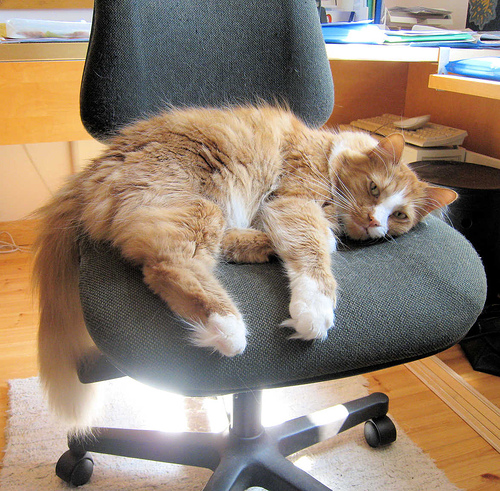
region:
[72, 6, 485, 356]
orange and white cat lying across gray office chair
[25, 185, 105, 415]
fluffy tail hanging off side of chair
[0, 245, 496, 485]
white rug on wood floor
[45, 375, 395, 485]
black chair base and wheels on rug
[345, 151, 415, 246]
cat with grouchy expression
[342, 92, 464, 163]
mouse and keyboard on box in corner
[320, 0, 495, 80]
desk filled with papers, notebook, pens and artwork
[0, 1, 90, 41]
plastic container with flat item inside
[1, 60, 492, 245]
wooden wall underneath desk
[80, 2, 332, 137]
woven fabric with fuzzy loops on back of chair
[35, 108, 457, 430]
A brown cat lying on a chair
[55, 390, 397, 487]
Base of the revolving chair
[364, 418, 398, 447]
One of the castors under the chair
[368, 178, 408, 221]
Open yellow eyes of the cat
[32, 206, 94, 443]
Furry bushy tail of the cat hanging down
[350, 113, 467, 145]
A white keyboard behind the cat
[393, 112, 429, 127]
A computer mouse in inverted position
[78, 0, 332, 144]
The backrest of the chair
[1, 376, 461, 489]
A white rug under the chair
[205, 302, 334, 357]
The white colored paws of the cat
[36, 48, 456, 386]
on orange cat on a chair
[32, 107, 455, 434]
an orange cat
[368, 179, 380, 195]
the eye of the cat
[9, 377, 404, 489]
a white rug on the floor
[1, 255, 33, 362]
the hardwood floor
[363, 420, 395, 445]
a wheel on the chair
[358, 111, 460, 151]
a keyboard and a computer mouse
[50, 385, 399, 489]
the bottom of the chair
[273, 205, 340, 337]
the arm of the cat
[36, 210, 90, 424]
the tail of the cat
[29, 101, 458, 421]
long haired orange and white cat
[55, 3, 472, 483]
a gray office chair with black casters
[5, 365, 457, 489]
white area rug under the chair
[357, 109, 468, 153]
computer keyboard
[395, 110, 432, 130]
mouse on the keyboard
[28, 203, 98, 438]
the cat's tail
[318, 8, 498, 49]
papers on the desk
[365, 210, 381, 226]
cat's pink nose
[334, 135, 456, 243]
the cat's head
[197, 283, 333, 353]
two paws with white fur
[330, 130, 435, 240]
a face of this cat seems upset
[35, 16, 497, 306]
cat on a office chair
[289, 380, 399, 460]
casters on an office chair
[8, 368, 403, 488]
the chair is on a rug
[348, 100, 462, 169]
a keyboard and mouse behind the cat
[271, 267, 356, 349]
white cat paws on the chair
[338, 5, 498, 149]
looks to be a desk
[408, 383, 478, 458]
hard wood flooring under chair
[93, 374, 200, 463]
sunlight comes in very bright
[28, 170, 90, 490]
a very fluffy cat tail